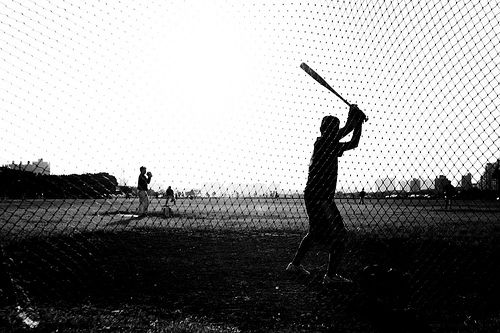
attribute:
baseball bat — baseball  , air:
[299, 62, 368, 122]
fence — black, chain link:
[44, 53, 496, 251]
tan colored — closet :
[184, 47, 431, 254]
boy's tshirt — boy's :
[273, 123, 392, 238]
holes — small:
[138, 197, 265, 231]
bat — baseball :
[302, 64, 364, 117]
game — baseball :
[108, 54, 375, 291]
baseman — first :
[440, 183, 461, 210]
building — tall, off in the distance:
[2, 157, 51, 174]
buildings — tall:
[0, 158, 52, 177]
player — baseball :
[136, 166, 154, 216]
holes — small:
[210, 201, 230, 224]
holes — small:
[174, 146, 235, 208]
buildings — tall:
[405, 152, 498, 217]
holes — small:
[70, 121, 132, 206]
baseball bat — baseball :
[297, 58, 367, 120]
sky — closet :
[95, 35, 287, 147]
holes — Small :
[215, 223, 252, 250]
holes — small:
[1, 0, 496, 330]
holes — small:
[0, 1, 500, 236]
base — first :
[131, 200, 169, 227]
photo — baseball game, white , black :
[9, 4, 479, 331]